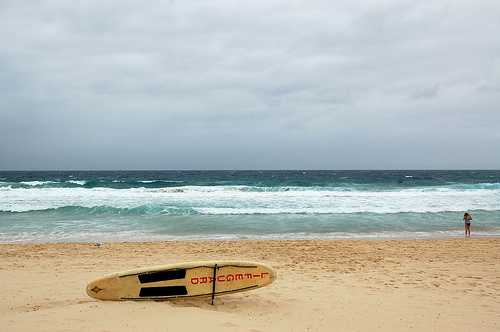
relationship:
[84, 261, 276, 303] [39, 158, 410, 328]
device on beach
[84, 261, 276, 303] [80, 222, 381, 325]
device on sand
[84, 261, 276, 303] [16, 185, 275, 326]
device on beach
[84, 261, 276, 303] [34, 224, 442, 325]
device on sand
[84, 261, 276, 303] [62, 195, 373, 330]
device on beach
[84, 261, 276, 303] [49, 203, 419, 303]
device on sand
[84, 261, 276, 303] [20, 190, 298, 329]
device on beach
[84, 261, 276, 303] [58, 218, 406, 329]
device on sand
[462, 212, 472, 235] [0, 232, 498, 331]
girl standing on beach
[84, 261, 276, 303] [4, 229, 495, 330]
device sitting on sand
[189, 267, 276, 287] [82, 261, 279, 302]
red letters on device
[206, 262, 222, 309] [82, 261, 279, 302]
black handles on device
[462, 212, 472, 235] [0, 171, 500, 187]
girl near blue water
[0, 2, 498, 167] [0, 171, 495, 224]
cloud over water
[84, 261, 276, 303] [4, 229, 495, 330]
device in sand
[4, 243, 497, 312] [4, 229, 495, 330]
tracks in sand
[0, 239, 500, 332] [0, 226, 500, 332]
brown sand on beach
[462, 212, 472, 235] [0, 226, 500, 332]
girl standing on beach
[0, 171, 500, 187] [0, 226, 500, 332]
blue water crashing on beach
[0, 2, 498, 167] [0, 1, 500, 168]
cloud in cloudy sky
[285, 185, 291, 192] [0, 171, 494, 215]
person in ocean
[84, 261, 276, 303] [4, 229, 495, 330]
device stuck in sand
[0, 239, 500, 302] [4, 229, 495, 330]
tracks in sand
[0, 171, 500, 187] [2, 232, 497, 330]
blue water crashing on to shore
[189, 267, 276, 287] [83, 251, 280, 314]
red letters on surfboard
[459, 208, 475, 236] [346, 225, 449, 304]
girl on sand